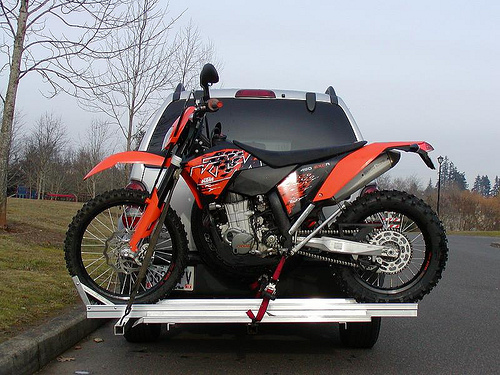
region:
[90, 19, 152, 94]
branches of a tree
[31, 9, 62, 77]
branches of a tree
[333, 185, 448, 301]
the wheel of a motorcycle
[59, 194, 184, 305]
the wheel of a motorcycle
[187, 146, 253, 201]
a gas tank of a motorcycle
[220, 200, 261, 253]
the engine of a motorcycle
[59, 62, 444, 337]
a motorcycle on the back of vehicle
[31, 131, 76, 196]
trees in the distance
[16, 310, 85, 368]
the cement curb of a road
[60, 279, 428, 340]
a motorcycle carrier on a vehicle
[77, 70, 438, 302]
dirt bike on trailer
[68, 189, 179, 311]
tire on dirt bike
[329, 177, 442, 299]
tire on dirt bike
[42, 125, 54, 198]
tree with no leaves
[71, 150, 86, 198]
tree with no leaves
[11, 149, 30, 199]
tree with no leaves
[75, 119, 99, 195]
tree with no leaves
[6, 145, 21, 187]
tree with no leaves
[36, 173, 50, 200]
tree with no leaves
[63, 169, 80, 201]
tree with no leaves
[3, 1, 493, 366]
Exterior shot, on overcast day.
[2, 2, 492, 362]
Outdoor view of residential street, with car and bike shown.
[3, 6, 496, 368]
Depiction of vehicles, and manipulated landscape, suggesting late fall, early winter.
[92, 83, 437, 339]
Silver SUV, carrying red and black motorcyle in mint condition.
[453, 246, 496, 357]
Dark, rainswept asphalt.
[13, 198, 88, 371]
Curb and patchy grass.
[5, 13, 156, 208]
Barren trees and cars in distance.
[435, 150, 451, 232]
Old-fashioned lamppost in distance.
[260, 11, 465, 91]
Sullen, grey-blue sky.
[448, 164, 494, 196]
Evergreens, beyond lamppost.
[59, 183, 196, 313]
Front tire on motorcycle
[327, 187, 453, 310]
Back tire on motorcycle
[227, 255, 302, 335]
Strap on dirt bike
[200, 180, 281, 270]
Engine on dirt bike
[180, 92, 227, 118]
Handlebars on dirt bike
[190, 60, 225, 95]
Rear view on dirt bike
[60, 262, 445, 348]
Trailer holding dirt bike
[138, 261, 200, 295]
License plate on SUV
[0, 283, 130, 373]
Curb next to SUV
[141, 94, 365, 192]
Back window of SUV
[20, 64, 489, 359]
an suv hauling a motorcycle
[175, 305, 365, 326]
a silver metal bumper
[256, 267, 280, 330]
red strap securing the motorcycle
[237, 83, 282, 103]
red brake light on the SUV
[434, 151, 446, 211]
a black street light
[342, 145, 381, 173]
red back fender on the motorcycle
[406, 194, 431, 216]
thick black tread on the tire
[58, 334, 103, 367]
brown leaves next to the curb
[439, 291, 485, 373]
gray asphalt on the street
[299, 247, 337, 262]
thick silver bike chain